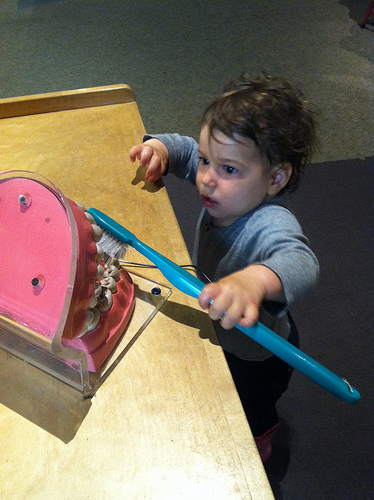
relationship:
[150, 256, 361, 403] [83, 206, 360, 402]
handle on tooth brush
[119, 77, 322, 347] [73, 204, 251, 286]
child holds toothbrush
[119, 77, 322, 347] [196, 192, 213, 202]
child brushes teeth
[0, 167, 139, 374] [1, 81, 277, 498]
teeth on table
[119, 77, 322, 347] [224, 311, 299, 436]
child wears pants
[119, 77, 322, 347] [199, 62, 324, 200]
child has hair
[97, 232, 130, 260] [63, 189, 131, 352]
bristles touching teeth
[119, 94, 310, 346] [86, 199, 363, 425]
child holding brush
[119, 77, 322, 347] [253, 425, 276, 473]
child wearing socks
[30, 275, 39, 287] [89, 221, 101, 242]
bolt in tooth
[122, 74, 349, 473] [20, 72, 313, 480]
baby at table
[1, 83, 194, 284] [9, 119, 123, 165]
table made of wood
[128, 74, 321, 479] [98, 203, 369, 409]
baby holding toothbrush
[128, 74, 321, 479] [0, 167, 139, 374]
baby brushing teeth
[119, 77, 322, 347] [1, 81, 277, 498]
child standing by table